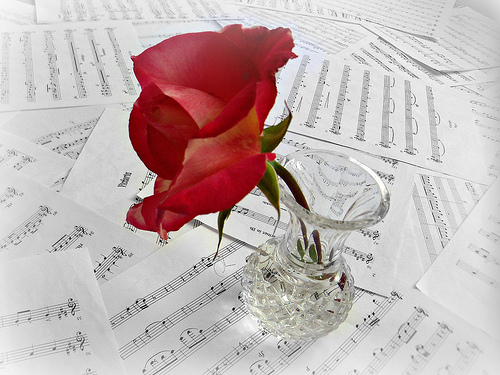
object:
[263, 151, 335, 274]
green stem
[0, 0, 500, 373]
paper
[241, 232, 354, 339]
water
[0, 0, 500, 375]
writing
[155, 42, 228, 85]
red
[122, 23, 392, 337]
flower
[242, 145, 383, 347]
clear vase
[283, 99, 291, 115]
bent tip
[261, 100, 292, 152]
leaf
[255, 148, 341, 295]
stem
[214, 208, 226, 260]
leaves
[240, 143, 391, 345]
vase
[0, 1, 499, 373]
music sheets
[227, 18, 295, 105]
edge